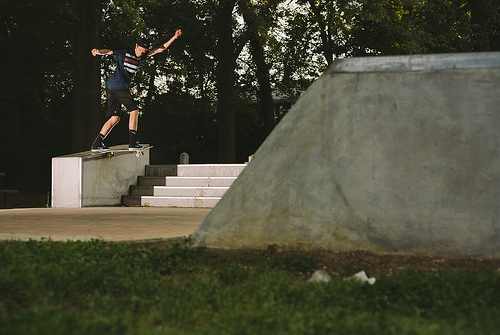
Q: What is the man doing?
A: Skateboarding.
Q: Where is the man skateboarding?
A: Down some steps.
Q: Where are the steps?
A: Under the man.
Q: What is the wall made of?
A: COncrete.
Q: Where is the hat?
A: On the man.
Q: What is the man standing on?
A: Skateboard.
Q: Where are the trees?
A: Behind the steps.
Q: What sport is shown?
A: Skateboarding.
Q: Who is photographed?
A: A skateboarder.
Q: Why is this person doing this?
A: For a trick.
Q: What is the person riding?
A: A skateboard.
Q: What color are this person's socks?
A: Black.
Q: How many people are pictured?
A: One.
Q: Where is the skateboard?
A: On the wall.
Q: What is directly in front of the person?
A: A set of steps.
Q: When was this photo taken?
A: During the daytime.